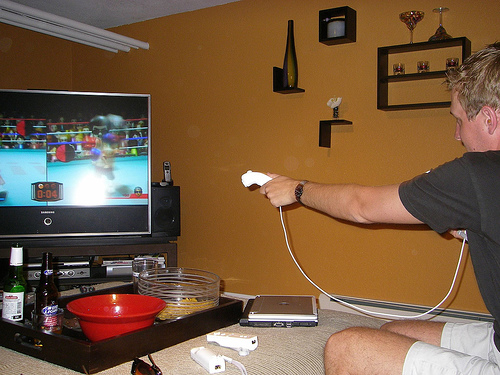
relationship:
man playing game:
[254, 32, 499, 373] [1, 92, 151, 237]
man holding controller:
[254, 32, 499, 373] [236, 165, 274, 192]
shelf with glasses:
[373, 31, 473, 117] [385, 54, 460, 72]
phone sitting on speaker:
[158, 158, 174, 186] [151, 186, 180, 231]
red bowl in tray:
[64, 293, 166, 342] [1, 280, 243, 373]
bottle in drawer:
[30, 251, 67, 343] [0, 282, 244, 374]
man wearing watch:
[258, 42, 500, 375] [292, 180, 309, 205]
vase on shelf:
[278, 18, 301, 89] [271, 64, 303, 95]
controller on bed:
[188, 343, 248, 373] [0, 295, 386, 374]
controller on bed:
[206, 329, 259, 356] [0, 295, 386, 374]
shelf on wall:
[376, 36, 471, 111] [71, 2, 498, 316]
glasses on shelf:
[393, 63, 406, 76] [376, 36, 471, 111]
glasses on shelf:
[416, 60, 430, 73] [376, 36, 471, 111]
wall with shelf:
[71, 2, 498, 316] [376, 36, 471, 111]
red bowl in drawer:
[67, 294, 166, 343] [0, 268, 247, 373]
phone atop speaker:
[163, 160, 172, 182] [149, 184, 182, 234]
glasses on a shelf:
[394, 4, 469, 42] [376, 36, 471, 111]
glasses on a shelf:
[428, 0, 453, 38] [376, 36, 471, 111]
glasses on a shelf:
[445, 53, 459, 73] [376, 36, 471, 111]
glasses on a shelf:
[412, 55, 433, 75] [376, 36, 471, 111]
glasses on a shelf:
[392, 60, 408, 74] [376, 36, 471, 111]